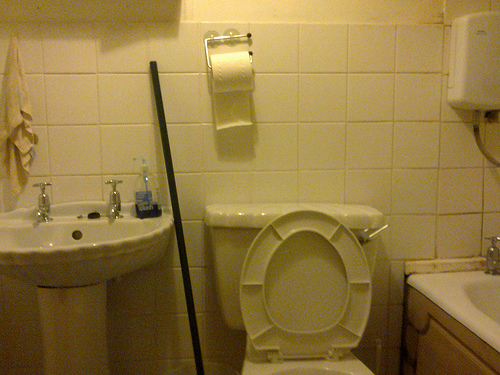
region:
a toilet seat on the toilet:
[237, 208, 372, 361]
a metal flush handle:
[358, 221, 389, 243]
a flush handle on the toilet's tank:
[355, 222, 390, 245]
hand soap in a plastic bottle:
[130, 155, 162, 220]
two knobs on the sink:
[31, 178, 126, 224]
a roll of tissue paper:
[209, 49, 255, 131]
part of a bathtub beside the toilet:
[400, 234, 498, 374]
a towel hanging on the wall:
[0, 30, 35, 200]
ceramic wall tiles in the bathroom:
[267, 25, 439, 174]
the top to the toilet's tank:
[204, 203, 386, 230]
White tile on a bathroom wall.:
[0, 23, 497, 374]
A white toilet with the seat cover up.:
[205, 201, 389, 374]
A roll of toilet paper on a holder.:
[203, 30, 258, 132]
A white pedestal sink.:
[0, 198, 175, 373]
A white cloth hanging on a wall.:
[0, 36, 37, 200]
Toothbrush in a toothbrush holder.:
[132, 150, 153, 215]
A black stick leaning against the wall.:
[147, 57, 207, 374]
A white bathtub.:
[404, 261, 499, 355]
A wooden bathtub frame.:
[400, 266, 499, 374]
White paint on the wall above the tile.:
[0, 0, 499, 23]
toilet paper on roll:
[202, 59, 248, 91]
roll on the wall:
[205, 31, 255, 56]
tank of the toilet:
[203, 191, 258, 224]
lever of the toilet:
[366, 229, 395, 250]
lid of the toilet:
[240, 234, 355, 345]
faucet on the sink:
[99, 168, 120, 218]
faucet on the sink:
[30, 168, 58, 220]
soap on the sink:
[129, 155, 166, 212]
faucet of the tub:
[465, 229, 494, 276]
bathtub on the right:
[463, 282, 493, 316]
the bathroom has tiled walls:
[8, 5, 496, 367]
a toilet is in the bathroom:
[199, 203, 386, 374]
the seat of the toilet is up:
[237, 208, 371, 364]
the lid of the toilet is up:
[270, 231, 349, 323]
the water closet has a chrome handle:
[201, 198, 385, 338]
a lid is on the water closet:
[201, 196, 388, 238]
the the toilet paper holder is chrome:
[204, 10, 256, 90]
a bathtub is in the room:
[399, 260, 499, 372]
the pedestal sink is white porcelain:
[1, 175, 177, 373]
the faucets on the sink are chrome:
[27, 172, 127, 228]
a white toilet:
[195, 195, 390, 371]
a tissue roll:
[195, 25, 260, 135]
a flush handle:
[353, 218, 390, 243]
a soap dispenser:
[130, 155, 155, 211]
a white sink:
[3, 180, 173, 373]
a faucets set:
[27, 173, 125, 226]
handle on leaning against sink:
[145, 58, 207, 373]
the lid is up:
[237, 203, 372, 353]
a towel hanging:
[2, 31, 38, 201]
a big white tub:
[406, 237, 498, 367]